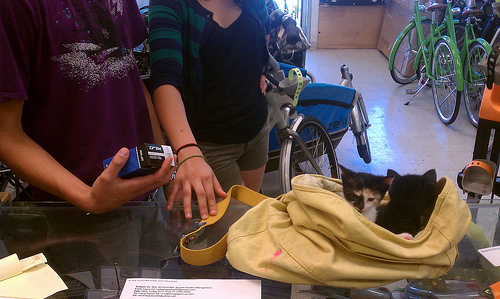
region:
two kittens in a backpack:
[332, 139, 486, 248]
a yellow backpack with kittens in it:
[210, 143, 472, 297]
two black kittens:
[311, 135, 478, 256]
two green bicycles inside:
[381, 3, 491, 123]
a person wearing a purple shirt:
[0, 3, 179, 178]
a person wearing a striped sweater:
[155, 4, 278, 110]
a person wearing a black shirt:
[129, 5, 289, 142]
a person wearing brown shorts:
[171, 102, 354, 224]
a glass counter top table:
[9, 180, 316, 297]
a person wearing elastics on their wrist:
[134, 87, 313, 224]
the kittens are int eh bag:
[285, 142, 461, 289]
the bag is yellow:
[230, 185, 412, 296]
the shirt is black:
[181, 24, 316, 174]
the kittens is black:
[382, 173, 420, 227]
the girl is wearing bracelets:
[152, 120, 239, 213]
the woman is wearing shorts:
[173, 92, 276, 202]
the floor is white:
[377, 107, 424, 189]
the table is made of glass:
[26, 215, 188, 285]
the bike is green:
[397, 15, 478, 105]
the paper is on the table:
[108, 276, 245, 296]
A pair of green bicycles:
[374, 4, 498, 134]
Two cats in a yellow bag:
[308, 163, 452, 253]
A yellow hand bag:
[172, 157, 475, 288]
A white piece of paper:
[104, 271, 271, 296]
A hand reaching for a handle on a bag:
[147, 117, 236, 227]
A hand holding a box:
[70, 130, 186, 236]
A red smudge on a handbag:
[240, 231, 303, 282]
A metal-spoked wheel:
[277, 101, 351, 196]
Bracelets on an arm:
[155, 123, 230, 187]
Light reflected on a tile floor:
[335, 94, 400, 176]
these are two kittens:
[338, 169, 436, 228]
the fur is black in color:
[401, 180, 418, 223]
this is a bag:
[252, 215, 325, 264]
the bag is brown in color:
[245, 210, 287, 248]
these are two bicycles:
[404, 15, 489, 73]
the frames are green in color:
[424, 26, 466, 41]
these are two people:
[18, 1, 283, 186]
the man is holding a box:
[88, 136, 178, 208]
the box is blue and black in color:
[130, 146, 152, 165]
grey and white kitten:
[327, 158, 393, 228]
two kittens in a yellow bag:
[325, 139, 455, 246]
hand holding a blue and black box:
[84, 126, 188, 220]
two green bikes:
[379, 0, 497, 149]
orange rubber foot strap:
[457, 150, 495, 195]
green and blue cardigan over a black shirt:
[140, 0, 276, 155]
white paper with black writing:
[120, 270, 264, 297]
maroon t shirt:
[0, 1, 155, 171]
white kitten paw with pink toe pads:
[393, 230, 423, 247]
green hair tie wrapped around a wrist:
[172, 150, 215, 170]